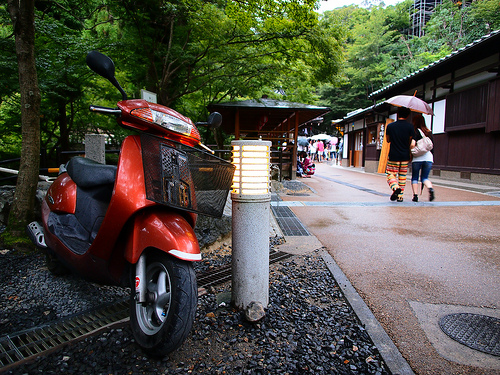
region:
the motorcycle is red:
[9, 98, 251, 298]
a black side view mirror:
[83, 47, 117, 80]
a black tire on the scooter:
[126, 252, 201, 357]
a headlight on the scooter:
[128, 100, 203, 145]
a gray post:
[223, 135, 278, 312]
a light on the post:
[228, 138, 274, 202]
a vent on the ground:
[1, 244, 290, 367]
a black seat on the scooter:
[64, 153, 119, 191]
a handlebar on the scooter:
[86, 103, 122, 118]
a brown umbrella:
[381, 87, 439, 120]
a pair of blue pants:
[409, 157, 436, 189]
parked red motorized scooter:
[21, 51, 241, 358]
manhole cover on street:
[435, 299, 499, 356]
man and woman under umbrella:
[376, 86, 442, 205]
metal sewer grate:
[272, 196, 309, 241]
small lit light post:
[225, 135, 283, 321]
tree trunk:
[2, 8, 57, 235]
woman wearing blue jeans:
[405, 105, 442, 205]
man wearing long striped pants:
[385, 100, 410, 202]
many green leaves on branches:
[255, 17, 341, 93]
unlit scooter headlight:
[143, 106, 198, 134]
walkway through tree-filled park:
[70, 2, 475, 372]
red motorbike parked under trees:
[40, 75, 226, 347]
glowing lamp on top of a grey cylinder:
[222, 127, 298, 322]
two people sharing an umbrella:
[350, 72, 445, 217]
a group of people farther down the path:
[297, 121, 337, 166]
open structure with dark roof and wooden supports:
[200, 81, 320, 187]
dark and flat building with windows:
[370, 21, 490, 186]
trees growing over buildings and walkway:
[265, 0, 490, 112]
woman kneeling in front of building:
[285, 137, 320, 182]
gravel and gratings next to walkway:
[46, 188, 394, 368]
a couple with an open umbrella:
[375, 86, 435, 197]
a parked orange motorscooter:
[22, 50, 227, 355]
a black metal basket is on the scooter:
[137, 130, 232, 225]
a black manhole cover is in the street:
[440, 305, 496, 355]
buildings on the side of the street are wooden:
[200, 20, 495, 190]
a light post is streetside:
[226, 135, 271, 320]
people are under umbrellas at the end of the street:
[290, 127, 340, 173]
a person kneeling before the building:
[296, 145, 316, 175]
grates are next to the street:
[271, 200, 308, 240]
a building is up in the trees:
[393, 0, 495, 46]